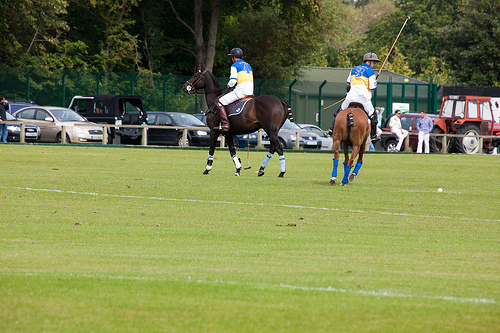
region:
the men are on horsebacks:
[168, 15, 414, 193]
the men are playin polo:
[175, 43, 409, 187]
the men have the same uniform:
[146, 55, 397, 190]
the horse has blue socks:
[313, 153, 369, 185]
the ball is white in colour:
[429, 180, 446, 193]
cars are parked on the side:
[45, 95, 192, 152]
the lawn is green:
[125, 213, 373, 320]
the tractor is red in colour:
[438, 101, 495, 139]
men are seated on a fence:
[387, 107, 433, 151]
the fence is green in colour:
[71, 73, 178, 97]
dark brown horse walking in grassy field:
[181, 62, 296, 180]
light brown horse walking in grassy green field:
[327, 97, 382, 189]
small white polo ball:
[435, 185, 445, 194]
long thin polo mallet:
[366, 8, 414, 101]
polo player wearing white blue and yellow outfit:
[341, 48, 383, 150]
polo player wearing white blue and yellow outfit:
[211, 46, 257, 134]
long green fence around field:
[0, 62, 497, 149]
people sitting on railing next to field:
[368, 103, 443, 153]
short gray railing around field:
[0, 118, 498, 155]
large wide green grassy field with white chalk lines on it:
[0, 138, 498, 331]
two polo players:
[180, 3, 423, 195]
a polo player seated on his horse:
[176, 37, 306, 185]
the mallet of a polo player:
[360, 5, 426, 92]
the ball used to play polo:
[435, 176, 449, 196]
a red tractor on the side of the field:
[412, 80, 499, 145]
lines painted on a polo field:
[21, 158, 451, 313]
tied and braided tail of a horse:
[345, 109, 358, 141]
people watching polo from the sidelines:
[387, 102, 436, 152]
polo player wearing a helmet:
[224, 48, 246, 60]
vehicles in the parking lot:
[20, 78, 200, 153]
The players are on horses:
[142, 40, 397, 181]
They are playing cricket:
[76, 35, 478, 242]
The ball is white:
[432, 179, 447, 198]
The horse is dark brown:
[167, 101, 293, 152]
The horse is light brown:
[337, 108, 367, 145]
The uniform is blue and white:
[211, 53, 253, 118]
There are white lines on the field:
[6, 181, 491, 231]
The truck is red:
[442, 92, 490, 136]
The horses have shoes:
[190, 148, 367, 202]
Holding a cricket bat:
[332, 13, 409, 119]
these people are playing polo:
[74, 45, 472, 229]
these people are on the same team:
[168, 21, 423, 210]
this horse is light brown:
[311, 91, 397, 196]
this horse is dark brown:
[164, 58, 294, 197]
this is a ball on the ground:
[385, 176, 462, 205]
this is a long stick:
[360, 3, 417, 90]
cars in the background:
[12, 81, 194, 166]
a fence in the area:
[302, 74, 437, 110]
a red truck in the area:
[428, 86, 499, 145]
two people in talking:
[388, 101, 445, 171]